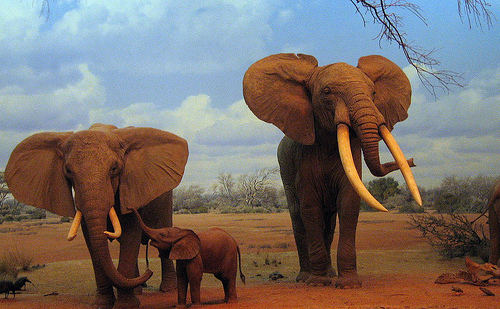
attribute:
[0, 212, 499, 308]
dirt — red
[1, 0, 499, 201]
sky — blue, cloudy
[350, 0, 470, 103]
branch — partial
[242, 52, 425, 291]
elephant — red, large, gray, grey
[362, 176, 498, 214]
trees — green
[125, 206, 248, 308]
elephant — red, baby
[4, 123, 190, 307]
elephant — medium, red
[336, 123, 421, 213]
horns — large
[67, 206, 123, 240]
tusk — white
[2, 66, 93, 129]
clouds — white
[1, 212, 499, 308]
ground — red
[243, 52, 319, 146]
ear — stretched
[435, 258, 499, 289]
bones — white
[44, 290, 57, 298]
twigs — brown